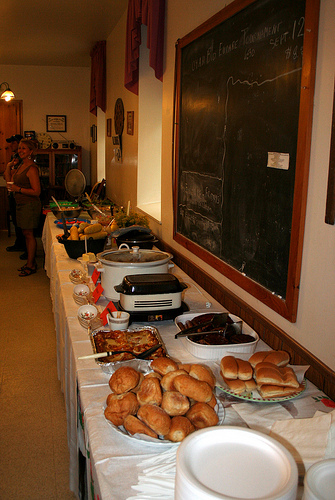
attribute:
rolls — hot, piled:
[104, 354, 221, 442]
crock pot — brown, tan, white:
[94, 245, 173, 303]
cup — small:
[5, 179, 15, 194]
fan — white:
[62, 167, 89, 199]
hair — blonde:
[17, 136, 33, 153]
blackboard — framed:
[169, 2, 321, 325]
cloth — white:
[39, 208, 334, 500]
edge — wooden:
[169, 32, 183, 244]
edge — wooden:
[170, 227, 301, 324]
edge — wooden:
[280, 1, 320, 323]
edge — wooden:
[171, 1, 255, 50]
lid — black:
[113, 272, 190, 296]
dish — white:
[105, 394, 226, 445]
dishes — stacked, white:
[171, 425, 300, 500]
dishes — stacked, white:
[301, 458, 335, 499]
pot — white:
[93, 240, 177, 305]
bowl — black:
[56, 232, 109, 257]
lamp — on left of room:
[0, 79, 15, 105]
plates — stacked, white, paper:
[171, 423, 298, 498]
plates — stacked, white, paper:
[302, 455, 334, 500]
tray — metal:
[85, 325, 173, 375]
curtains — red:
[121, 0, 167, 95]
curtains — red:
[85, 39, 109, 115]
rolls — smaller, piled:
[217, 347, 303, 401]